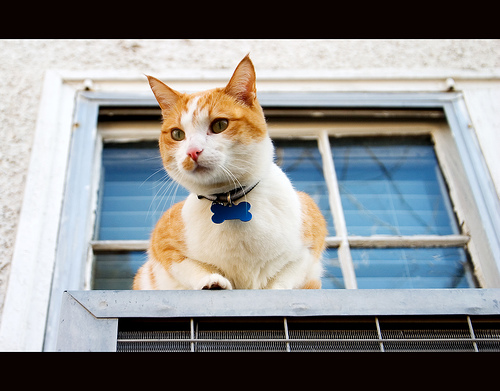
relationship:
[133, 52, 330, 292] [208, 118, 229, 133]
cat left eye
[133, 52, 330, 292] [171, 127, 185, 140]
cat right eye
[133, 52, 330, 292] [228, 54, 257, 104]
cat left ear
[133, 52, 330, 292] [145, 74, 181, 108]
cat right ear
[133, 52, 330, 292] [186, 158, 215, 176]
cat with mouth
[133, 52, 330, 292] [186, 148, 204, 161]
cat with nose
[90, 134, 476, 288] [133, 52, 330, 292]
window behind cat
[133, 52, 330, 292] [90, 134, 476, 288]
cat in front of window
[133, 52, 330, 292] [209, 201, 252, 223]
cat with blue tag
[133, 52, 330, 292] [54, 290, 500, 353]
cat on air conditioner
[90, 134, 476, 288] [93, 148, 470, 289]
window with blinds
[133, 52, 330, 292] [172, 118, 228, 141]
cat with eyes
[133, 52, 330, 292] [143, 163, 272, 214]
cat with whisker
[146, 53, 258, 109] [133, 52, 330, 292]
ears on cat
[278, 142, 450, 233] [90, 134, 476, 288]
reflection in window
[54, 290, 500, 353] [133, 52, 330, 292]
air conditioner under cat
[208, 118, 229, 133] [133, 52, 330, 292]
eye of cat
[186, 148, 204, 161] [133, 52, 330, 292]
nose of cat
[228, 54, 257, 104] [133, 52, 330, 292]
ear of cat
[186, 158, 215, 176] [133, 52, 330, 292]
mouth of cat